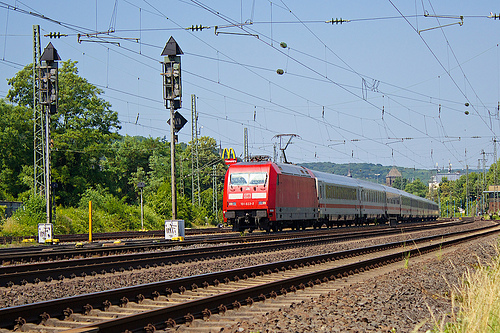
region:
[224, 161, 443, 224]
long red and grey train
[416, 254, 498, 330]
tuft of long yellow grass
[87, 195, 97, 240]
skinny yellow painted metal pole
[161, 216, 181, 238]
small rectangle metal box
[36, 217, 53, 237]
small rectangle metal box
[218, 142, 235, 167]
red white and yellow golden McDonalds sign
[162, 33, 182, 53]
metal black triangle sign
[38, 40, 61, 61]
metal black triangle sign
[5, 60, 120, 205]
large leafy green tree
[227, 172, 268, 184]
train windshield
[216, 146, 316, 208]
front of train is red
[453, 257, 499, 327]
grass is very dry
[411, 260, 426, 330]
gravel on the side track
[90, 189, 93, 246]
the pole is yellow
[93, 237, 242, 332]
three sets of railtrack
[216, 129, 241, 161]
MacDonald sign in the background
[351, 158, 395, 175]
trees in the background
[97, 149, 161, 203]
green trees to the left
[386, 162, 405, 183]
tower in the background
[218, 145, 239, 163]
Mcdonalds golden arches sign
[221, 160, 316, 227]
Red train engine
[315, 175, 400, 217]
White train cars with red stripes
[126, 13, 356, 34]
Ten electrical train wires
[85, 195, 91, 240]
yellow pole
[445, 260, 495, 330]
Yellow and green grass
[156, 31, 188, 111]
Pyramid topped Train signal light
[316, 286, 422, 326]
Multi colored rocky ground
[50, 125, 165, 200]
Green trees and plants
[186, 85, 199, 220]
Metal electrical support tower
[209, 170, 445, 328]
The train is on the tracks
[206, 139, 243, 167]
McDonald's is in the back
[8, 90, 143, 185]
The trees are green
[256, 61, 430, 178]
The sky is clear and blue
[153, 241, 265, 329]
Tracks for the train to ride on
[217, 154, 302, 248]
The front of the train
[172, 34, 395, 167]
Wires above the train tracks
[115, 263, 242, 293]
Gravel in between the train tracks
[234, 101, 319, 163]
Power lines in the background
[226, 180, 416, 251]
The train is silver and red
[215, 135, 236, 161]
A McDonald's sign in the distance.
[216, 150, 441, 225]
A passenger train.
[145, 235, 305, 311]
Train tracks embedded in gravel.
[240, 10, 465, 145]
A web of power lines.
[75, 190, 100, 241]
A yellow metal pole.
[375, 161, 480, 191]
A town in the background.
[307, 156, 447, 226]
A group of silver passenger cars.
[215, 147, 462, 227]
The train is red and silver.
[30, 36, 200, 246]
Two metal signs.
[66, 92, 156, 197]
A forest.